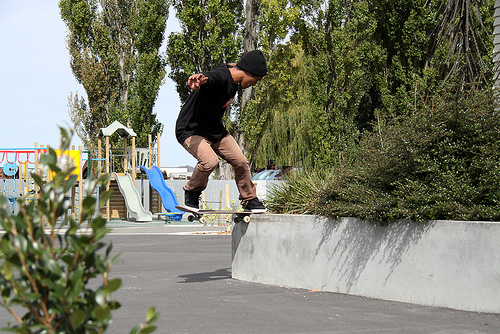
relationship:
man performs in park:
[173, 47, 267, 214] [2, 125, 499, 333]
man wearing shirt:
[173, 47, 267, 214] [171, 64, 241, 149]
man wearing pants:
[173, 47, 267, 214] [172, 132, 262, 203]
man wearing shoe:
[173, 44, 271, 219] [239, 195, 269, 218]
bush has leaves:
[312, 92, 500, 229] [315, 90, 499, 231]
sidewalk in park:
[5, 233, 499, 334] [2, 125, 499, 333]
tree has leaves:
[57, 1, 174, 151] [54, 0, 174, 149]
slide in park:
[134, 163, 188, 226] [2, 125, 499, 333]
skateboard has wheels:
[168, 201, 265, 227] [184, 213, 254, 225]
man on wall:
[173, 47, 267, 214] [228, 211, 499, 314]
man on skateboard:
[173, 44, 271, 219] [168, 201, 265, 227]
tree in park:
[57, 1, 174, 151] [2, 125, 499, 333]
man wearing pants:
[173, 44, 271, 219] [172, 132, 262, 203]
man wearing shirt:
[173, 44, 271, 219] [171, 64, 241, 149]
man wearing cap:
[173, 44, 271, 219] [233, 44, 273, 79]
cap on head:
[233, 44, 273, 79] [232, 46, 270, 96]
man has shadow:
[173, 44, 271, 219] [173, 263, 238, 289]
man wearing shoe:
[173, 44, 271, 219] [180, 186, 205, 212]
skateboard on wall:
[168, 201, 265, 227] [228, 211, 499, 314]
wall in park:
[228, 211, 499, 314] [2, 125, 499, 333]